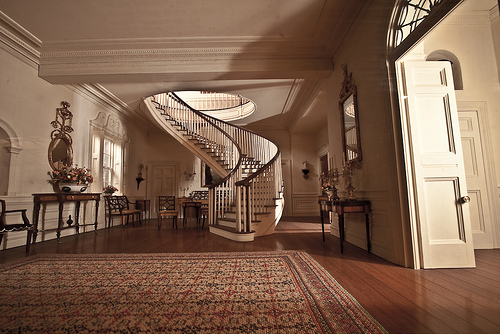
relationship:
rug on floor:
[3, 255, 393, 330] [1, 217, 499, 332]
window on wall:
[94, 138, 120, 193] [1, 31, 147, 251]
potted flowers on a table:
[53, 164, 93, 184] [33, 186, 110, 218]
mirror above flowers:
[23, 102, 102, 194] [49, 159, 101, 185]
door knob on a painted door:
[451, 188, 477, 209] [379, 54, 478, 269]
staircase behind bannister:
[156, 91, 278, 231] [183, 95, 280, 185]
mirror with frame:
[35, 113, 87, 190] [46, 99, 74, 172]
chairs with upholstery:
[103, 191, 141, 223] [104, 207, 142, 221]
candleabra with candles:
[316, 165, 339, 200] [314, 161, 339, 177]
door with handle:
[397, 55, 478, 276] [458, 191, 469, 206]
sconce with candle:
[288, 142, 340, 207] [295, 157, 312, 173]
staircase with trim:
[121, 53, 301, 247] [168, 94, 282, 194]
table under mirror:
[318, 197, 375, 255] [328, 65, 372, 167]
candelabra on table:
[340, 154, 357, 203] [317, 193, 376, 253]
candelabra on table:
[322, 163, 338, 202] [317, 193, 376, 253]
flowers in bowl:
[53, 162, 92, 181] [52, 182, 99, 192]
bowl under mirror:
[52, 182, 99, 192] [47, 127, 74, 173]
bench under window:
[103, 193, 141, 226] [90, 135, 125, 193]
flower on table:
[48, 160, 95, 187] [26, 186, 102, 242]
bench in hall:
[103, 186, 132, 221] [2, 0, 498, 330]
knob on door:
[455, 188, 473, 208] [397, 55, 478, 276]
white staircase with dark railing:
[151, 91, 287, 239] [168, 90, 278, 185]